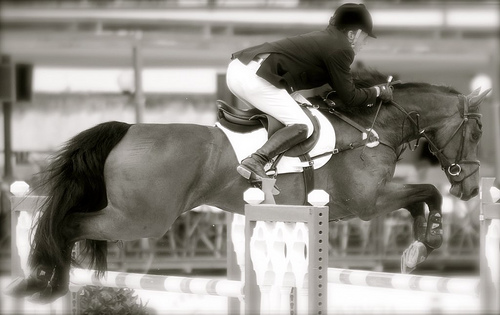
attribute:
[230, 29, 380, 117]
jacket — black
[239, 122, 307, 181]
shoes — dark 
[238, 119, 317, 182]
boots — dark, colored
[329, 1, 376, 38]
hat — black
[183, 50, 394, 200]
pants — white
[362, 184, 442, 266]
leg — curled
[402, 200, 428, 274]
leg — curled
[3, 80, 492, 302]
horse — wears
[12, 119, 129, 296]
tail — black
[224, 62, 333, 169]
white pants — worn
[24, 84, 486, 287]
horse — jumping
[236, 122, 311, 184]
boot — knee high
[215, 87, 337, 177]
pad — light